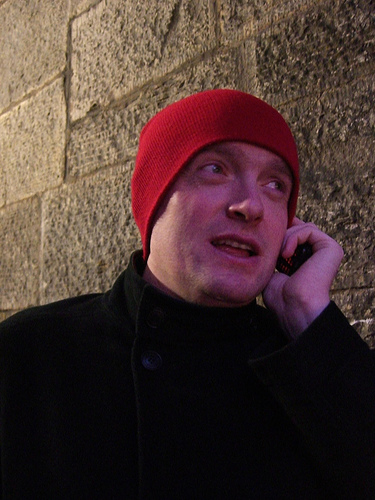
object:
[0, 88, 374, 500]
man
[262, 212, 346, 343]
hand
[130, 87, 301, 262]
bennie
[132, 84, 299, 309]
head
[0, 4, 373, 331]
wall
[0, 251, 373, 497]
coat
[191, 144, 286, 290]
amused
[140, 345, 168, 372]
button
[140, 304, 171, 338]
button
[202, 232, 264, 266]
mouth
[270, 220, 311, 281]
use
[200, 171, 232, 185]
bag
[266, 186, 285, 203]
bag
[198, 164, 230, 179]
eye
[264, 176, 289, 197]
eye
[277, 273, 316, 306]
bony prominence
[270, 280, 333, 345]
wrist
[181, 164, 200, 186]
crows feet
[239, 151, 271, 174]
hairs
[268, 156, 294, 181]
eyebrow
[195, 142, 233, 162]
eyebrow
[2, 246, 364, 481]
winter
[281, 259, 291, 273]
buttons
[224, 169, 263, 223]
nose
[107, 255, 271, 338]
collar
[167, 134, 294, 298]
face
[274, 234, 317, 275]
cellphone